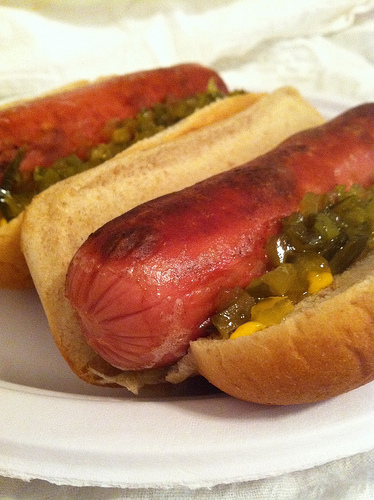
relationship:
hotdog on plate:
[71, 94, 372, 375] [0, 371, 372, 485]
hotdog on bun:
[19, 86, 373, 407] [187, 263, 372, 424]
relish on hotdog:
[267, 184, 373, 263] [71, 94, 372, 375]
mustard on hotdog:
[218, 320, 269, 353] [71, 94, 372, 375]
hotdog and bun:
[7, 66, 223, 178] [0, 65, 264, 291]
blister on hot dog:
[221, 142, 310, 208] [66, 101, 358, 354]